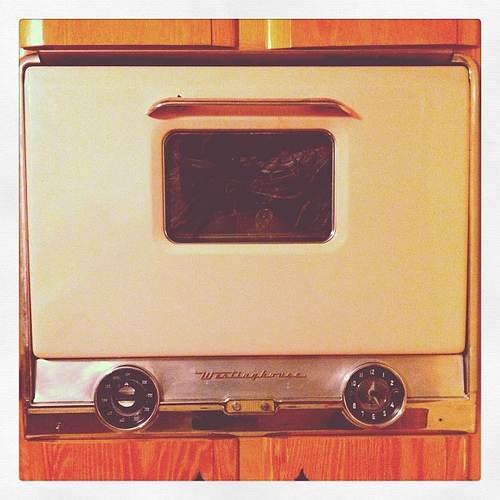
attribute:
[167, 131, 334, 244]
part — clear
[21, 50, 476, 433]
stove — silver, white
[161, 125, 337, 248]
part of the stove — clear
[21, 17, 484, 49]
wood — carved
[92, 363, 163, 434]
knob — circular, black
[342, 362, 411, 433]
clock — circular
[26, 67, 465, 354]
door — beige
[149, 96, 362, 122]
handle — metal, steel, shiny, silver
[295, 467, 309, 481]
point — black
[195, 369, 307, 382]
name — engraved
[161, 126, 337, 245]
window — small, glass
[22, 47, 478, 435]
oven — branded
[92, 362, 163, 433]
dial — black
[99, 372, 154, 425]
numbers — white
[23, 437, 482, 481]
cabinet — wood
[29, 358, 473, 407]
part — silver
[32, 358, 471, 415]
base — metal, steel, shiny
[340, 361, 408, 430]
knob — black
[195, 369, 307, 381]
logo — silver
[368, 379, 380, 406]
hands — silver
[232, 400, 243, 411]
bolt — silver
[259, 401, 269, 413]
bolt — silver